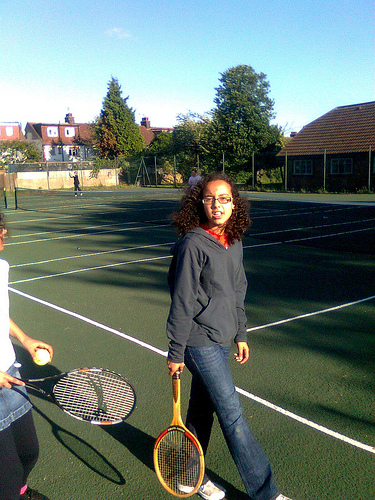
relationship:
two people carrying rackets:
[0, 190, 370, 491] [37, 357, 210, 485]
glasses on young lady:
[198, 194, 233, 209] [161, 174, 293, 495]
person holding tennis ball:
[1, 213, 46, 496] [36, 351, 52, 370]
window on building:
[290, 159, 313, 180] [277, 99, 372, 198]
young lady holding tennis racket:
[161, 174, 293, 495] [151, 374, 204, 500]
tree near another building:
[90, 76, 143, 162] [25, 109, 161, 160]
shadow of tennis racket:
[43, 426, 132, 490] [21, 367, 134, 425]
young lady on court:
[161, 174, 293, 495] [0, 190, 370, 491]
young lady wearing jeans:
[161, 174, 293, 495] [171, 345, 279, 494]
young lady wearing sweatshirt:
[161, 174, 293, 495] [158, 234, 251, 357]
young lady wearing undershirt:
[161, 174, 293, 495] [202, 230, 232, 249]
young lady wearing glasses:
[161, 174, 293, 495] [198, 194, 233, 209]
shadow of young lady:
[107, 410, 167, 467] [161, 174, 293, 495]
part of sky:
[197, 19, 342, 67] [2, 4, 371, 102]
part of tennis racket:
[64, 373, 126, 416] [21, 367, 134, 425]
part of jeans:
[228, 424, 269, 491] [171, 345, 279, 494]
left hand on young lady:
[235, 347, 255, 366] [161, 174, 293, 495]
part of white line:
[99, 316, 145, 350] [8, 266, 171, 359]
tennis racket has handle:
[151, 374, 204, 500] [168, 375, 184, 422]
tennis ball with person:
[36, 351, 52, 370] [1, 213, 46, 496]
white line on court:
[8, 266, 171, 359] [0, 190, 370, 491]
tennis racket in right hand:
[151, 374, 204, 500] [163, 358, 186, 381]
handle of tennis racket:
[168, 375, 184, 422] [151, 374, 204, 500]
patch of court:
[47, 218, 165, 295] [0, 190, 370, 491]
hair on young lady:
[172, 191, 251, 240] [161, 174, 293, 495]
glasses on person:
[198, 194, 233, 209] [161, 174, 293, 495]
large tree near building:
[200, 61, 283, 161] [277, 99, 372, 198]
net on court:
[0, 176, 27, 225] [0, 190, 370, 491]